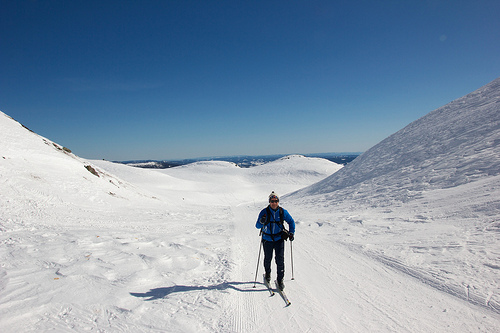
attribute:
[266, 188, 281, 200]
cap — white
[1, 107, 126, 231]
hill — snowy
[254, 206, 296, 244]
jacket — blue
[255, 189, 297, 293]
man — skiing, one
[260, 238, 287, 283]
pants — black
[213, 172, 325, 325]
pathway — snowy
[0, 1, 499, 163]
sky — clear, blue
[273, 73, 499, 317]
slope — white, steep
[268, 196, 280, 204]
sunglasses — black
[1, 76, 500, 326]
snow — drifts, white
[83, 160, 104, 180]
rock — tan